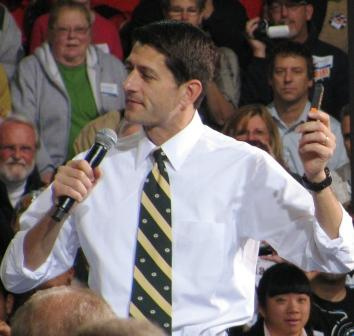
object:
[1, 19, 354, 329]
man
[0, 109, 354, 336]
shirt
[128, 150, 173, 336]
tie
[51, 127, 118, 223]
microphone